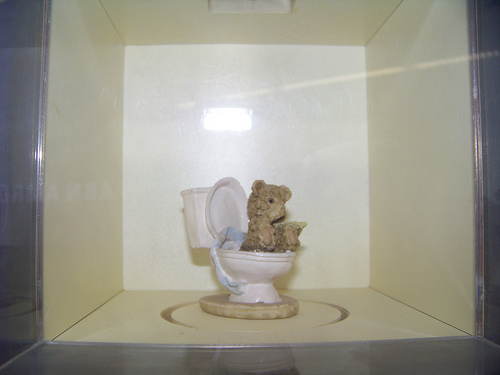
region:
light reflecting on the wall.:
[190, 93, 257, 137]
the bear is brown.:
[242, 175, 300, 259]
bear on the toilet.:
[172, 172, 307, 301]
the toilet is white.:
[174, 177, 296, 299]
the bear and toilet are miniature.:
[172, 179, 308, 306]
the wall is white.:
[116, 33, 376, 290]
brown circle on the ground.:
[154, 290, 354, 335]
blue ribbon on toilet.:
[207, 224, 255, 292]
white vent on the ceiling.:
[205, 0, 297, 22]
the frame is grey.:
[1, 0, 498, 371]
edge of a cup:
[242, 280, 272, 294]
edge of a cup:
[262, 255, 297, 265]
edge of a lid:
[196, 188, 216, 221]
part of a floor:
[355, 284, 399, 321]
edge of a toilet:
[225, 240, 265, 271]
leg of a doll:
[283, 227, 301, 252]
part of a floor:
[311, 276, 343, 326]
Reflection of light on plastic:
[197, 102, 256, 131]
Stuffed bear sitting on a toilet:
[247, 182, 304, 249]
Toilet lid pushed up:
[203, 175, 248, 244]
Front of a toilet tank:
[183, 187, 221, 249]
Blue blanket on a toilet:
[209, 219, 243, 297]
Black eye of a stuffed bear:
[268, 195, 275, 205]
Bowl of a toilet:
[217, 252, 294, 278]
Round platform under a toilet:
[196, 293, 301, 320]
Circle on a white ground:
[157, 296, 357, 331]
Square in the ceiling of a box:
[203, 2, 300, 17]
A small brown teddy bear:
[236, 172, 320, 251]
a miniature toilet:
[179, 178, 323, 308]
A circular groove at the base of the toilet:
[159, 286, 361, 336]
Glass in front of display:
[56, 1, 479, 336]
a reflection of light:
[179, 80, 264, 143]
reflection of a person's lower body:
[191, 342, 338, 374]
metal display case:
[3, 9, 55, 374]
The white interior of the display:
[63, 3, 460, 332]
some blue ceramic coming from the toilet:
[208, 233, 238, 291]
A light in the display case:
[206, 0, 308, 21]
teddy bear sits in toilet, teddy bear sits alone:
[173, 163, 312, 322]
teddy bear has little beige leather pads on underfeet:
[257, 222, 301, 250]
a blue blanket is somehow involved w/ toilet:
[208, 226, 249, 300]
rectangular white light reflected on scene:
[156, 85, 261, 139]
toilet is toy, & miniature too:
[175, 175, 311, 320]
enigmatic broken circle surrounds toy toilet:
[156, 287, 351, 338]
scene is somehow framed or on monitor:
[1, 1, 498, 373]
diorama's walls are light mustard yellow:
[39, 1, 479, 338]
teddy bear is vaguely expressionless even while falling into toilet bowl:
[238, 176, 310, 259]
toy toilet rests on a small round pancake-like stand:
[202, 286, 304, 321]